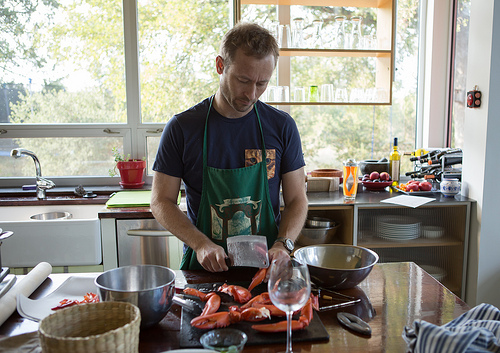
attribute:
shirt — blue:
[150, 93, 305, 241]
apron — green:
[181, 93, 277, 269]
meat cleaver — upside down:
[223, 233, 268, 268]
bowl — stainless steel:
[294, 245, 381, 289]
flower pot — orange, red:
[116, 157, 147, 187]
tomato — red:
[420, 181, 433, 191]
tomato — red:
[406, 183, 418, 192]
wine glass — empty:
[266, 255, 311, 352]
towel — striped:
[400, 302, 499, 352]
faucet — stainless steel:
[10, 147, 56, 201]